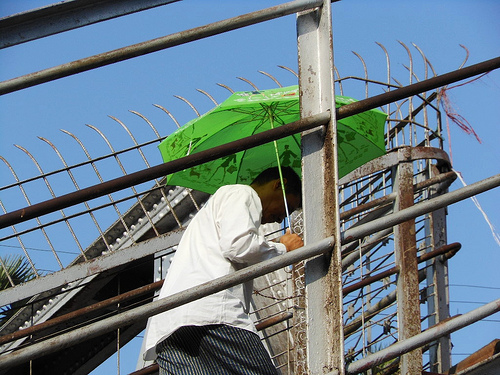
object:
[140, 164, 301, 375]
man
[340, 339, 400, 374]
tree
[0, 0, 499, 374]
metal railing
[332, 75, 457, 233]
poles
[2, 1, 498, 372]
railing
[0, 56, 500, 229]
pole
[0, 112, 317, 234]
rusty bar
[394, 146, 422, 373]
metal post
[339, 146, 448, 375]
poles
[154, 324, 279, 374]
bottoms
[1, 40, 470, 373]
fence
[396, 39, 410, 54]
spike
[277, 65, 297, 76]
spike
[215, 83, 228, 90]
spike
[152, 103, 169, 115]
spike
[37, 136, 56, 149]
spike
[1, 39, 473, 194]
top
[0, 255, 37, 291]
leaves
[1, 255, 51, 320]
palm trees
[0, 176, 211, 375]
stairs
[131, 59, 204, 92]
sky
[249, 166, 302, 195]
black hair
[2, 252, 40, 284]
palm leaves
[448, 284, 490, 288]
lines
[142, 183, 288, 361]
shirt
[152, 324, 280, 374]
pants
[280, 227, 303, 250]
hand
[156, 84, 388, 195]
umbrella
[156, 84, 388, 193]
canopy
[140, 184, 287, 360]
white coat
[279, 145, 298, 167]
characters